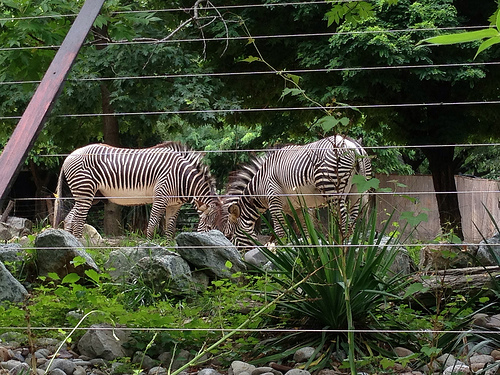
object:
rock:
[127, 252, 202, 302]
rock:
[172, 230, 249, 282]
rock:
[103, 239, 174, 279]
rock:
[0, 227, 97, 281]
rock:
[243, 241, 285, 269]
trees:
[0, 0, 499, 246]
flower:
[285, 134, 498, 311]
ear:
[227, 203, 241, 221]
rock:
[75, 321, 131, 362]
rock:
[37, 356, 74, 373]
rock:
[145, 362, 167, 373]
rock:
[37, 343, 53, 358]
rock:
[33, 353, 46, 363]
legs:
[140, 184, 187, 241]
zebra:
[52, 140, 242, 244]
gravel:
[0, 314, 497, 374]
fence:
[457, 173, 498, 238]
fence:
[378, 170, 438, 237]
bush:
[246, 179, 440, 374]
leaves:
[422, 64, 472, 87]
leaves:
[369, 41, 396, 58]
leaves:
[337, 15, 364, 29]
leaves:
[164, 88, 197, 100]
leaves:
[7, 55, 29, 77]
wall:
[377, 175, 438, 238]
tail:
[353, 143, 377, 219]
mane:
[151, 139, 221, 200]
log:
[412, 264, 499, 295]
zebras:
[52, 133, 371, 246]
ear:
[193, 200, 210, 212]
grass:
[0, 218, 499, 366]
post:
[0, 0, 109, 216]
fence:
[1, 0, 498, 372]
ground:
[15, 209, 299, 293]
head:
[193, 198, 242, 240]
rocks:
[0, 229, 249, 302]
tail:
[52, 160, 65, 230]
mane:
[226, 150, 273, 203]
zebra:
[221, 133, 375, 258]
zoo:
[0, 0, 499, 374]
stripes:
[284, 159, 313, 186]